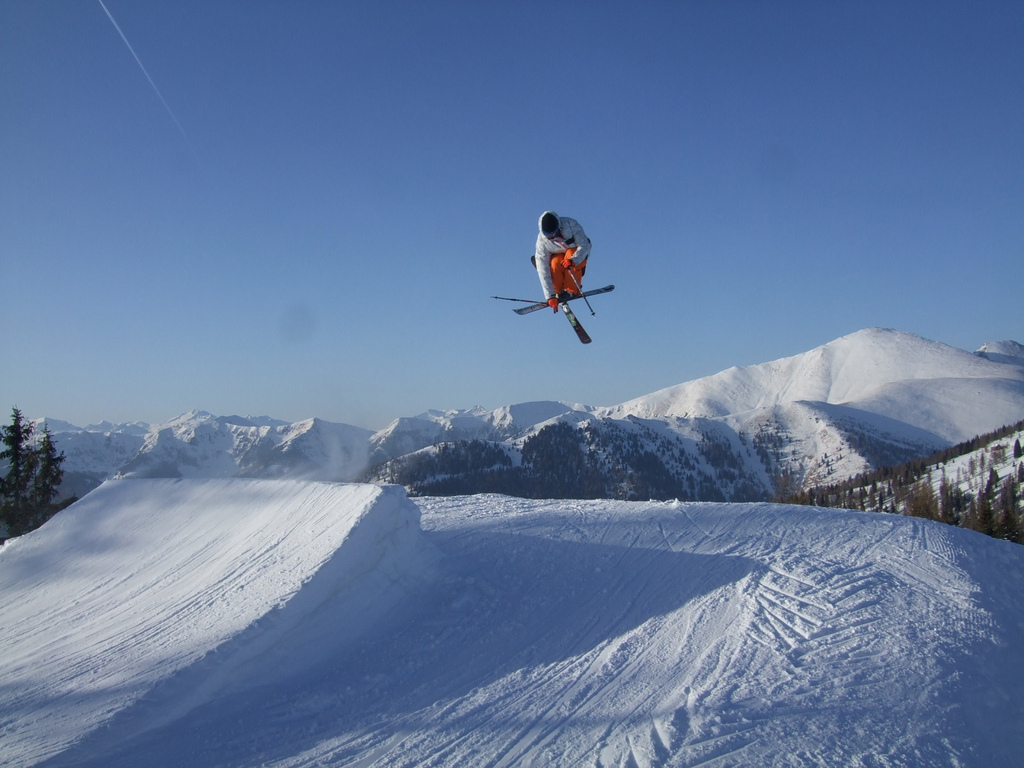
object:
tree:
[0, 406, 61, 538]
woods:
[0, 409, 65, 540]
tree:
[907, 482, 937, 517]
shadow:
[39, 484, 764, 768]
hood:
[539, 210, 563, 237]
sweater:
[536, 217, 593, 300]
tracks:
[769, 568, 829, 593]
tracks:
[250, 525, 296, 562]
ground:
[0, 471, 1024, 764]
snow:
[0, 479, 1024, 745]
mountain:
[373, 327, 1020, 498]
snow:
[803, 356, 978, 400]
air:
[198, 99, 482, 332]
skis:
[514, 285, 615, 315]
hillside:
[608, 328, 885, 408]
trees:
[539, 437, 575, 494]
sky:
[0, 0, 1022, 224]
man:
[536, 211, 593, 314]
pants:
[550, 249, 586, 294]